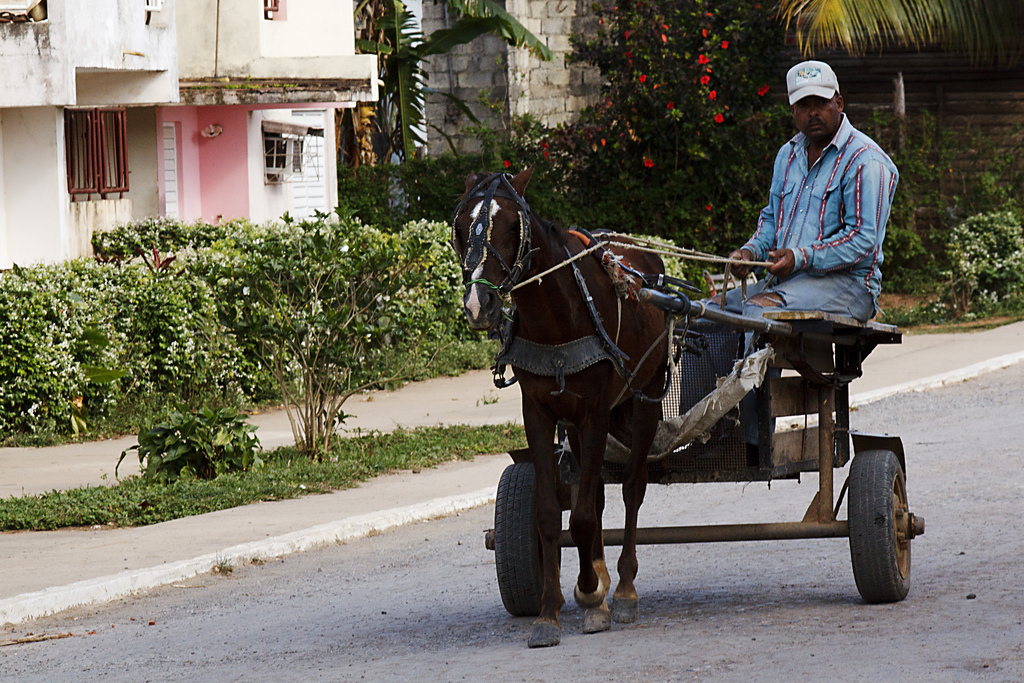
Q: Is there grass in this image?
A: Yes, there is grass.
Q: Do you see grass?
A: Yes, there is grass.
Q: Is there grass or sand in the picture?
A: Yes, there is grass.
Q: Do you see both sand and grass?
A: No, there is grass but no sand.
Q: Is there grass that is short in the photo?
A: Yes, there is short grass.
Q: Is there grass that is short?
A: Yes, there is grass that is short.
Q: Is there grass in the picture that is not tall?
A: Yes, there is short grass.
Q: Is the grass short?
A: Yes, the grass is short.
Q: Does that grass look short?
A: Yes, the grass is short.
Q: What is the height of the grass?
A: The grass is short.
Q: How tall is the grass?
A: The grass is short.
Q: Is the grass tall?
A: No, the grass is short.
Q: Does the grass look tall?
A: No, the grass is short.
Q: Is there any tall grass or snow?
A: No, there is grass but it is short.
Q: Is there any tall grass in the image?
A: No, there is grass but it is short.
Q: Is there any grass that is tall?
A: No, there is grass but it is short.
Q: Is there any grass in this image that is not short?
A: No, there is grass but it is short.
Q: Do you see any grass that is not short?
A: No, there is grass but it is short.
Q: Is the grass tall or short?
A: The grass is short.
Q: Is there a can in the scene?
A: No, there are no cans.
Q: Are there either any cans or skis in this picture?
A: No, there are no cans or skis.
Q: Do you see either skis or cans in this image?
A: No, there are no cans or skis.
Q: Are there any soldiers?
A: No, there are no soldiers.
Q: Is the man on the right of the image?
A: Yes, the man is on the right of the image.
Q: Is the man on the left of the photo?
A: No, the man is on the right of the image.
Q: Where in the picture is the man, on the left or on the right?
A: The man is on the right of the image.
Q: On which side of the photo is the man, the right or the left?
A: The man is on the right of the image.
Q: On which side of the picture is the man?
A: The man is on the right of the image.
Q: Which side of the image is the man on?
A: The man is on the right of the image.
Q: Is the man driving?
A: Yes, the man is driving.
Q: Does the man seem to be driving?
A: Yes, the man is driving.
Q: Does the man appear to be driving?
A: Yes, the man is driving.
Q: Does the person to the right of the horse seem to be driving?
A: Yes, the man is driving.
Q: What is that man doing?
A: The man is driving.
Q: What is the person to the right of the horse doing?
A: The man is driving.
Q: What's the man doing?
A: The man is driving.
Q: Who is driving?
A: The man is driving.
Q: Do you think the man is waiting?
A: No, the man is driving.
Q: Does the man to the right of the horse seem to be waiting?
A: No, the man is driving.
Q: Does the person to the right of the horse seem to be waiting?
A: No, the man is driving.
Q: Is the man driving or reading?
A: The man is driving.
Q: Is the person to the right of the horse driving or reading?
A: The man is driving.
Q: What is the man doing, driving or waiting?
A: The man is driving.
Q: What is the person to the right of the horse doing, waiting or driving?
A: The man is driving.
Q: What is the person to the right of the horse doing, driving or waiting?
A: The man is driving.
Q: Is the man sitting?
A: Yes, the man is sitting.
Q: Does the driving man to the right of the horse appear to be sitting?
A: Yes, the man is sitting.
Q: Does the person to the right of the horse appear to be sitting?
A: Yes, the man is sitting.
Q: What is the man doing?
A: The man is sitting.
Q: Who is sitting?
A: The man is sitting.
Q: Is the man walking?
A: No, the man is sitting.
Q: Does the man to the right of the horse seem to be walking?
A: No, the man is sitting.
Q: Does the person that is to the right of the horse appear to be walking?
A: No, the man is sitting.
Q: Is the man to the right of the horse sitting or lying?
A: The man is sitting.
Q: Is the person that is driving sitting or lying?
A: The man is sitting.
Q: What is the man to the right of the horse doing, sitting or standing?
A: The man is sitting.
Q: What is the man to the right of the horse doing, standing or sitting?
A: The man is sitting.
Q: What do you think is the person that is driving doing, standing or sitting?
A: The man is sitting.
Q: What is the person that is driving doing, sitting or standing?
A: The man is sitting.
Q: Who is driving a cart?
A: The man is driving a cart.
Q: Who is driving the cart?
A: The man is driving a cart.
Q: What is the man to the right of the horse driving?
A: The man is driving a cart.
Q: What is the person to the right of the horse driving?
A: The man is driving a cart.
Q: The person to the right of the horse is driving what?
A: The man is driving a cart.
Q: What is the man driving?
A: The man is driving a cart.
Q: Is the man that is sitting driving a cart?
A: Yes, the man is driving a cart.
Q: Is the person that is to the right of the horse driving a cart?
A: Yes, the man is driving a cart.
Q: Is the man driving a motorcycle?
A: No, the man is driving a cart.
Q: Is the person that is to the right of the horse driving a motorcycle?
A: No, the man is driving a cart.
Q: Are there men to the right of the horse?
A: Yes, there is a man to the right of the horse.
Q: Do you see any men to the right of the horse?
A: Yes, there is a man to the right of the horse.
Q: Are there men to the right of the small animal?
A: Yes, there is a man to the right of the horse.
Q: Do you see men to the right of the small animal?
A: Yes, there is a man to the right of the horse.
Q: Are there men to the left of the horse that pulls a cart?
A: No, the man is to the right of the horse.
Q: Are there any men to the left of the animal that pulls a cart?
A: No, the man is to the right of the horse.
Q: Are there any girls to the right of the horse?
A: No, there is a man to the right of the horse.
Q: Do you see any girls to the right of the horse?
A: No, there is a man to the right of the horse.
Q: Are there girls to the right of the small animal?
A: No, there is a man to the right of the horse.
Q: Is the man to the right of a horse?
A: Yes, the man is to the right of a horse.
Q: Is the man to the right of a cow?
A: No, the man is to the right of a horse.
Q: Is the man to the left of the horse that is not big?
A: No, the man is to the right of the horse.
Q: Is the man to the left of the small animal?
A: No, the man is to the right of the horse.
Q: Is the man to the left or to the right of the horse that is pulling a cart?
A: The man is to the right of the horse.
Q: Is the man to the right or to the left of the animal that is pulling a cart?
A: The man is to the right of the horse.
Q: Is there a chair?
A: No, there are no chairs.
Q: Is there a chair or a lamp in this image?
A: No, there are no chairs or lamps.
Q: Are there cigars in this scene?
A: No, there are no cigars.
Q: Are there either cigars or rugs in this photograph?
A: No, there are no cigars or rugs.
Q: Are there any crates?
A: No, there are no crates.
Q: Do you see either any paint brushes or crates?
A: No, there are no crates or paint brushes.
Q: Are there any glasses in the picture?
A: No, there are no glasses.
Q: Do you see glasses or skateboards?
A: No, there are no glasses or skateboards.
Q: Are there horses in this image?
A: Yes, there is a horse.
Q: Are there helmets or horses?
A: Yes, there is a horse.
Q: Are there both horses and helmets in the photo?
A: No, there is a horse but no helmets.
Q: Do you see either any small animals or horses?
A: Yes, there is a small horse.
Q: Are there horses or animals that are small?
A: Yes, the horse is small.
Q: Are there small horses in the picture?
A: Yes, there is a small horse.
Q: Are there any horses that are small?
A: Yes, there is a horse that is small.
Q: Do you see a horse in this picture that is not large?
A: Yes, there is a small horse.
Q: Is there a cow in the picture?
A: No, there are no cows.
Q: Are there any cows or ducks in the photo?
A: No, there are no cows or ducks.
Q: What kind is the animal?
A: The animal is a horse.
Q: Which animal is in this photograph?
A: The animal is a horse.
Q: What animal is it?
A: The animal is a horse.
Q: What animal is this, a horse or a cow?
A: This is a horse.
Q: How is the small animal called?
A: The animal is a horse.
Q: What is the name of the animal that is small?
A: The animal is a horse.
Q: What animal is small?
A: The animal is a horse.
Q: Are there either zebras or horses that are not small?
A: No, there is a horse but it is small.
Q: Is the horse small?
A: Yes, the horse is small.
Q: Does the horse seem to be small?
A: Yes, the horse is small.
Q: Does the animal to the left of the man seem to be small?
A: Yes, the horse is small.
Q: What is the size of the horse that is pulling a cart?
A: The horse is small.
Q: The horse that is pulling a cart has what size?
A: The horse is small.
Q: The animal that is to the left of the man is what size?
A: The horse is small.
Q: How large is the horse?
A: The horse is small.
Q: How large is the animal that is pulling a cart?
A: The horse is small.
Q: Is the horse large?
A: No, the horse is small.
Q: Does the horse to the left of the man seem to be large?
A: No, the horse is small.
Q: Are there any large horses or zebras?
A: No, there is a horse but it is small.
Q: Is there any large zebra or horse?
A: No, there is a horse but it is small.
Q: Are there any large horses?
A: No, there is a horse but it is small.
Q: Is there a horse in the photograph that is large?
A: No, there is a horse but it is small.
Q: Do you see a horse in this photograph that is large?
A: No, there is a horse but it is small.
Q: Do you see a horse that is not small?
A: No, there is a horse but it is small.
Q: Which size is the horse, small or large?
A: The horse is small.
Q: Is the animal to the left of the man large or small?
A: The horse is small.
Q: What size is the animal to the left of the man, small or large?
A: The horse is small.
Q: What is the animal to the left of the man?
A: The animal is a horse.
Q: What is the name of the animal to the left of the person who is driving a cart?
A: The animal is a horse.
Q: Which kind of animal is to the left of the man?
A: The animal is a horse.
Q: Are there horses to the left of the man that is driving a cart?
A: Yes, there is a horse to the left of the man.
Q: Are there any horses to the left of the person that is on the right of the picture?
A: Yes, there is a horse to the left of the man.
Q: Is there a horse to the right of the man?
A: No, the horse is to the left of the man.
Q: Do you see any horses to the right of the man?
A: No, the horse is to the left of the man.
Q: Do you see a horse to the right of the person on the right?
A: No, the horse is to the left of the man.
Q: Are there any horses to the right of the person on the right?
A: No, the horse is to the left of the man.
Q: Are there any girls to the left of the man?
A: No, there is a horse to the left of the man.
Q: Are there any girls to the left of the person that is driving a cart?
A: No, there is a horse to the left of the man.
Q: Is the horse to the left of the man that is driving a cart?
A: Yes, the horse is to the left of the man.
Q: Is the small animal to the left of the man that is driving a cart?
A: Yes, the horse is to the left of the man.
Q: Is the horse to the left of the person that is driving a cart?
A: Yes, the horse is to the left of the man.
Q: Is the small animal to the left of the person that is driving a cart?
A: Yes, the horse is to the left of the man.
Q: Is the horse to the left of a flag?
A: No, the horse is to the left of the man.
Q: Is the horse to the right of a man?
A: No, the horse is to the left of a man.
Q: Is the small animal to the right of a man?
A: No, the horse is to the left of a man.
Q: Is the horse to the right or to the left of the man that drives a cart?
A: The horse is to the left of the man.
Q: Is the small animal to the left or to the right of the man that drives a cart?
A: The horse is to the left of the man.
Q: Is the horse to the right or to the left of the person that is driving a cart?
A: The horse is to the left of the man.